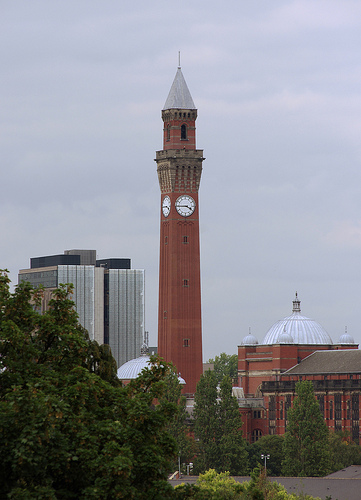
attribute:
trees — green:
[11, 305, 168, 496]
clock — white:
[175, 193, 195, 216]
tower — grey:
[162, 70, 193, 110]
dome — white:
[116, 339, 187, 386]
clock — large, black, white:
[161, 196, 172, 217]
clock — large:
[172, 196, 196, 215]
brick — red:
[174, 250, 185, 257]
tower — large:
[154, 47, 207, 395]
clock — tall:
[155, 189, 195, 220]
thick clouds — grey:
[243, 23, 330, 118]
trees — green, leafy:
[24, 276, 182, 465]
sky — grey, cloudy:
[286, 121, 336, 153]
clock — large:
[157, 173, 226, 230]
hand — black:
[175, 204, 187, 207]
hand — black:
[185, 206, 194, 211]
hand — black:
[160, 205, 167, 207]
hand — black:
[165, 205, 169, 210]